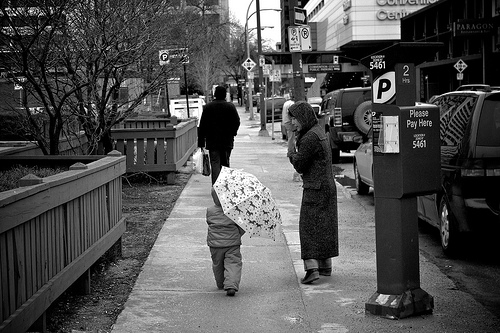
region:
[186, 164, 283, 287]
a child carrying a umbrella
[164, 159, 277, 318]
a child walking on a side walk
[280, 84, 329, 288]
a woman on a side walk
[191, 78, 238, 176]
a man carrying a white bag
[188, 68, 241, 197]
a man walking on a sidewalk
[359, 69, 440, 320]
a parking meter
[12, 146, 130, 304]
a wood fence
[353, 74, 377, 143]
a vehicle with the spare tire on the back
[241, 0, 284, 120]
street lamps on street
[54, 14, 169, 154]
a small tree with no leaves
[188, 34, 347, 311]
Busy city street sidewalk.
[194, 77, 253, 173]
Person dark clothing carrying bag.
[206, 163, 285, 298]
Small child warm clothing umbrella.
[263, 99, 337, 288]
Mother walking talking child.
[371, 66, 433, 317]
Two hour sidewalk parking meter.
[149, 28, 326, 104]
Numerous directional pole signs.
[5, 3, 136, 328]
Park trees wooden enclosures.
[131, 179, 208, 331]
Dusting snow along sidewalk.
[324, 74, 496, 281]
Vehicles stopped traffic road.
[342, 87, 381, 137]
Spare tire attached vehicle.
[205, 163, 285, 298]
Small child holding an umbrella.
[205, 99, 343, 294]
Child and a woman walking on the sidewalk.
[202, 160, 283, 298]
Child holding an open umbrella.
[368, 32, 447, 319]
Parking meter.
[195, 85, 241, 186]
Person with a bag walking on the sidewalk.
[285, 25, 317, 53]
No parking sign.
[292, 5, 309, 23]
One way street sign.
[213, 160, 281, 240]
Umbrella with horses on it.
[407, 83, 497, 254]
Dark colored SUV parked on the street.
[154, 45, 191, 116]
Parking lot sign.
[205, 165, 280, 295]
back of child with umbrella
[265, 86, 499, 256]
line of parked cars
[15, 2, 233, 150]
trees with no leaves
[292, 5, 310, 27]
sign with white arrow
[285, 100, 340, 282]
woman in long coat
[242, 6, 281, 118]
light on curved pole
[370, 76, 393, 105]
black letter on white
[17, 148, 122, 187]
three posts on fence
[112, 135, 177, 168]
flat boards of fence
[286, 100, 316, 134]
hood on woman's head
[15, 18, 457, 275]
a busy street scene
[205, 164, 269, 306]
this child is carrying an umbrella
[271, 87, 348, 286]
this woman is watching the child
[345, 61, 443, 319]
this is parking sign on the street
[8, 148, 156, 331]
a wooden area for plants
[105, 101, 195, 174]
a fenced off area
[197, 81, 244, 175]
a man walking with a brief case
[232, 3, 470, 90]
buildings in the background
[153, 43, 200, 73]
a parking sign on the street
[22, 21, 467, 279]
this picture is in black and white